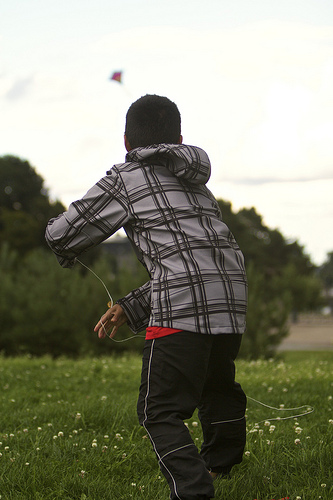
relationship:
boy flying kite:
[108, 90, 273, 466] [102, 66, 135, 90]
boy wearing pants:
[108, 90, 273, 466] [147, 340, 229, 431]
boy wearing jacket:
[108, 90, 273, 466] [141, 170, 224, 306]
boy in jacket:
[108, 90, 273, 466] [141, 170, 224, 306]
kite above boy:
[102, 66, 135, 90] [108, 90, 273, 466]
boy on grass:
[108, 90, 273, 466] [35, 375, 86, 441]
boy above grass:
[108, 90, 273, 466] [35, 375, 86, 441]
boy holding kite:
[108, 90, 273, 466] [102, 66, 135, 90]